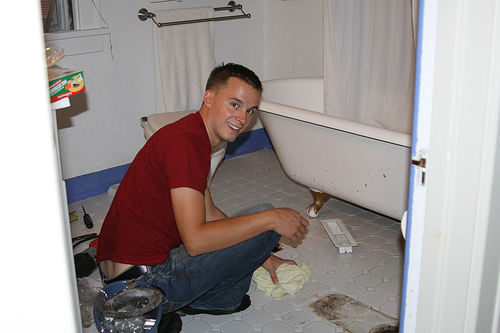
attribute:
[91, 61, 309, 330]
man — young, working, squatting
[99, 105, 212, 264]
shirt — red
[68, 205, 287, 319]
jeans — blue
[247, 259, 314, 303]
towel — yellow, cleaning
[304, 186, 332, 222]
foot — brass, metal, white, claw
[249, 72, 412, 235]
tub — white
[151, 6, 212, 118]
towel — white, hung, bath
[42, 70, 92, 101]
box — green, red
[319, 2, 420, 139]
shower curtain — white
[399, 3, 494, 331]
door — white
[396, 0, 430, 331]
edge — blue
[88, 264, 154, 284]
belt — leather, black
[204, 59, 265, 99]
hair — short, brown, dark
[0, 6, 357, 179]
wall — white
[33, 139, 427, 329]
floor — white, tile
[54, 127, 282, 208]
baseboard — purple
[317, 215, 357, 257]
air vent — removed